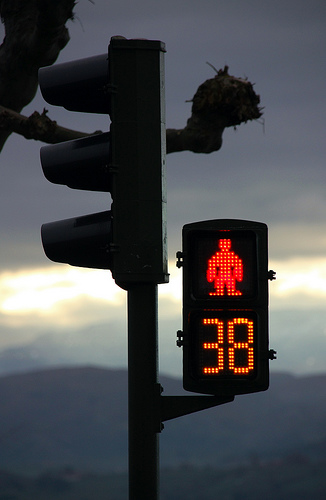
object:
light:
[181, 218, 270, 396]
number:
[201, 315, 255, 376]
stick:
[0, 105, 100, 147]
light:
[38, 34, 167, 289]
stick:
[165, 72, 267, 153]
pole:
[153, 393, 236, 418]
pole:
[113, 285, 170, 495]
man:
[206, 237, 241, 297]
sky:
[276, 107, 310, 262]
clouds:
[0, 262, 127, 327]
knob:
[265, 267, 279, 281]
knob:
[259, 346, 282, 364]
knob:
[174, 248, 190, 258]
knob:
[174, 259, 191, 271]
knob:
[175, 325, 187, 338]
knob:
[178, 339, 184, 347]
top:
[39, 50, 129, 113]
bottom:
[40, 201, 129, 292]